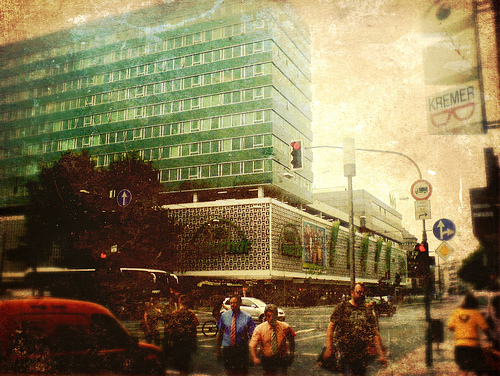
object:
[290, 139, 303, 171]
traffic light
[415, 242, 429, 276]
traffic light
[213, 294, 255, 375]
person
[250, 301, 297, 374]
person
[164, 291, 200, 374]
person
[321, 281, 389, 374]
person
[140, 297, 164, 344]
person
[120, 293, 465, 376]
street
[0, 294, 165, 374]
minivan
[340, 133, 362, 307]
pole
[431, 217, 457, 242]
sign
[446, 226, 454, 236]
arrow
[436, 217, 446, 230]
arrow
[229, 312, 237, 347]
tie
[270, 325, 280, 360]
tie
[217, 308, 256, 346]
shirt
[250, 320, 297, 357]
shirt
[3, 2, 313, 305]
building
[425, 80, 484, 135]
sign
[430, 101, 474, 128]
glasses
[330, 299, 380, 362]
top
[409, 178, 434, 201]
sign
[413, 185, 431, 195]
truck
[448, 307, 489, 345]
shirt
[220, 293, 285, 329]
car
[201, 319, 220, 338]
tire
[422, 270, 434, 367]
pole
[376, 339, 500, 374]
sidewalk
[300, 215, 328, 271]
sign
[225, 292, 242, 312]
head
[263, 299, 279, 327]
head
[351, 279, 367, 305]
head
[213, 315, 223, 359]
arm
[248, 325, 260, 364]
arm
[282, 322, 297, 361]
arm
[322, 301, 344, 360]
arm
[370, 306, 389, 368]
arm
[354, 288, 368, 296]
sunglasses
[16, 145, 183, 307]
tree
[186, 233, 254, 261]
name